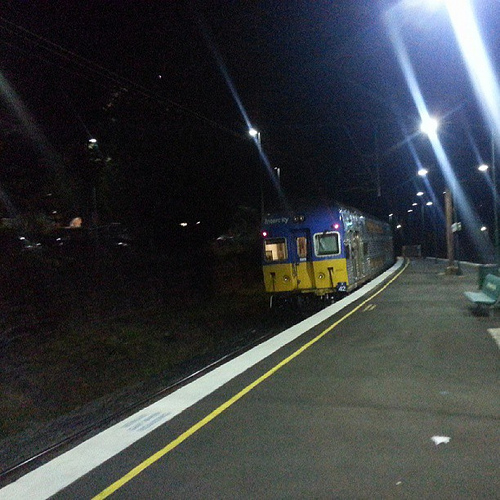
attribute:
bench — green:
[462, 266, 497, 319]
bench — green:
[456, 271, 498, 316]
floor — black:
[40, 243, 498, 497]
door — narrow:
[291, 227, 315, 292]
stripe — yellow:
[84, 256, 412, 499]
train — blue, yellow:
[254, 196, 399, 311]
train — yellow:
[261, 197, 393, 312]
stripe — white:
[2, 251, 406, 498]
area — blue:
[259, 197, 388, 260]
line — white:
[169, 356, 244, 397]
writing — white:
[263, 217, 293, 223]